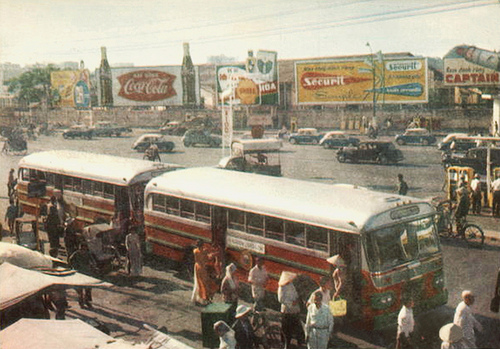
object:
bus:
[143, 165, 448, 331]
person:
[220, 262, 241, 307]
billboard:
[47, 60, 92, 111]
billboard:
[95, 42, 201, 107]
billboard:
[215, 49, 280, 106]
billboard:
[444, 46, 500, 86]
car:
[335, 140, 406, 164]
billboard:
[294, 56, 429, 105]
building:
[149, 85, 218, 110]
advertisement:
[95, 65, 199, 107]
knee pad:
[140, 170, 450, 317]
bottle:
[180, 42, 197, 105]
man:
[454, 186, 471, 239]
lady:
[326, 254, 353, 323]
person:
[125, 227, 143, 277]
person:
[395, 296, 415, 348]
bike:
[438, 199, 485, 248]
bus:
[13, 150, 186, 237]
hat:
[278, 271, 297, 287]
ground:
[349, 163, 381, 179]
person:
[438, 323, 476, 349]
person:
[305, 291, 335, 348]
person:
[306, 275, 332, 308]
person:
[276, 270, 305, 349]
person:
[453, 289, 486, 349]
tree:
[7, 70, 61, 124]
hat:
[326, 254, 344, 266]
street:
[0, 128, 497, 182]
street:
[0, 146, 499, 336]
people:
[190, 238, 220, 307]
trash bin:
[201, 301, 236, 349]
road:
[0, 130, 500, 182]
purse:
[329, 295, 347, 316]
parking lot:
[0, 110, 500, 349]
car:
[437, 133, 470, 150]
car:
[131, 134, 174, 152]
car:
[62, 125, 94, 139]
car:
[288, 127, 323, 144]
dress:
[193, 247, 219, 300]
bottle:
[99, 46, 113, 106]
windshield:
[362, 215, 441, 273]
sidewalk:
[0, 200, 393, 349]